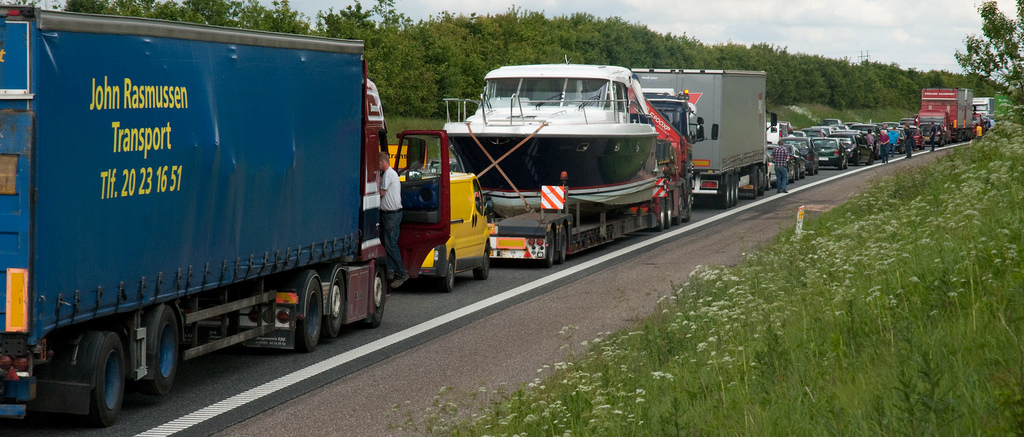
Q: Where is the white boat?
A: On a tow bed.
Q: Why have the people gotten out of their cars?
A: To see what is going on.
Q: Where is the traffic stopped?
A: Near a grassy field.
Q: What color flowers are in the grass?
A: White.